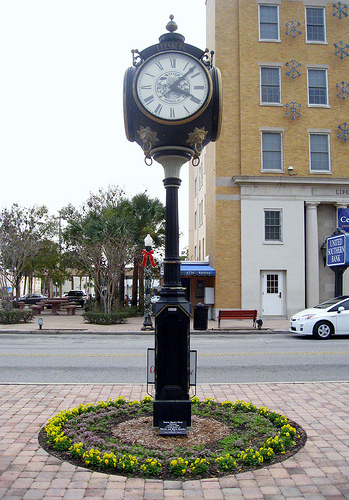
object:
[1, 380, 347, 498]
sidewalk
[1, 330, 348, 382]
street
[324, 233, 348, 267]
sign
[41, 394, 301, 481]
flower bed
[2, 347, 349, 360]
line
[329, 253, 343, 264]
bank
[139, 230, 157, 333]
lamplight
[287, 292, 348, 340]
car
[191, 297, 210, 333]
trash can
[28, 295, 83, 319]
table and seats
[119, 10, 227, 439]
clock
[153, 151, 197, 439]
pole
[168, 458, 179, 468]
flower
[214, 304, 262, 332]
bench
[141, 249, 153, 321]
decorations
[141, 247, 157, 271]
ribbon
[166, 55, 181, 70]
roman numeral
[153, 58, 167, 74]
roman numeral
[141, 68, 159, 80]
roman numeral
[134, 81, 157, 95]
roman numeral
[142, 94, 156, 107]
roman numeral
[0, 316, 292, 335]
sidewalk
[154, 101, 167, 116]
roman numeral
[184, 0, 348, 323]
building